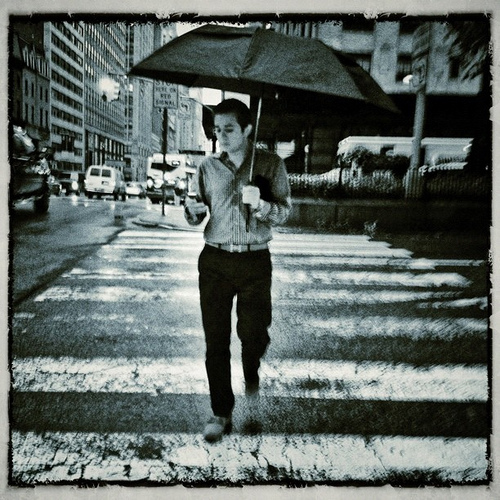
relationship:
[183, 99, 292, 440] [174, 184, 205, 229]
man holding cellphone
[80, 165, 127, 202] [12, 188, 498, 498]
van are on road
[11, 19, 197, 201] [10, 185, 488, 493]
building in street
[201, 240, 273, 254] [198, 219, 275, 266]
belt on wast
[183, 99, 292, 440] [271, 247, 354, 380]
man in street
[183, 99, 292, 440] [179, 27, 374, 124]
man holding umbrella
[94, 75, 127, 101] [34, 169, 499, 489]
trafficlight in street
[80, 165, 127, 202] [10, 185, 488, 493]
van in street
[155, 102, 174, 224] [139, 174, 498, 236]
street sign in sidewalk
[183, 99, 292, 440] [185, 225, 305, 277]
man wearing belt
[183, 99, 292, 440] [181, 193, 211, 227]
man has hand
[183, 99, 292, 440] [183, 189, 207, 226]
man holding phone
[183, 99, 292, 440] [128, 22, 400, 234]
man holding umbrella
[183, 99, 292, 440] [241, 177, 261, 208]
man has hand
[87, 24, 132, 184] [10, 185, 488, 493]
buildings alongside street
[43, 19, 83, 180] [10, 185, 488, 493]
buildings alongside street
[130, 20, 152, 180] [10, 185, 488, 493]
buildings alongside street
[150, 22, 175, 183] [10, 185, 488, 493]
buildings alongside street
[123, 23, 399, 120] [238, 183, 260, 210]
umbrella in hand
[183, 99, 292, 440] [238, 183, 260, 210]
man has hand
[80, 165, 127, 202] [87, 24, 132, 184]
van in front of buildings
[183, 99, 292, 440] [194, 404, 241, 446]
man wearing shoe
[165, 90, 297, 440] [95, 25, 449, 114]
man holding umbrella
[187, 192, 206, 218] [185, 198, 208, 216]
cellphone in hand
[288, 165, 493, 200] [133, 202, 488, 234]
fence near sidewalk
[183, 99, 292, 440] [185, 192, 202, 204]
man looking at h phone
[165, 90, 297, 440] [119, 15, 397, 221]
man carrying umbrella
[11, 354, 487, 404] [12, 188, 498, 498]
line on road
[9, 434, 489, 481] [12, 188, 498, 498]
line on road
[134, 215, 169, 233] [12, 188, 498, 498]
curb on road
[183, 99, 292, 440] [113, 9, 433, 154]
man carrying umbrella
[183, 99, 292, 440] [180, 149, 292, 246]
man wearing shirt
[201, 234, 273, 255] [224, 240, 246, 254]
belt has buckle